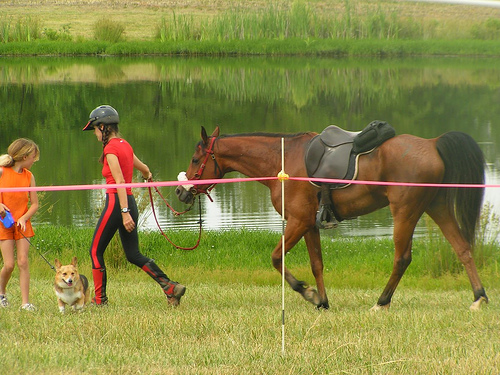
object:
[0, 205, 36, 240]
shorts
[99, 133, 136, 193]
shirt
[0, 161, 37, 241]
outfit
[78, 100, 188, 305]
girl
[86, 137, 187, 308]
outfit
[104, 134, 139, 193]
top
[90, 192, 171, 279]
pants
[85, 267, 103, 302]
stripe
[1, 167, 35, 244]
jumper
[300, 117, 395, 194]
harness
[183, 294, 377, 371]
grass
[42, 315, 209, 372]
grass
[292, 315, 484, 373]
grass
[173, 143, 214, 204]
horse's face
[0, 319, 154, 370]
grass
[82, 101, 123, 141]
woman's head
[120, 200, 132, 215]
woman's wrist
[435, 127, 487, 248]
thick tail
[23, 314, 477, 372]
field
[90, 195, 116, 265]
red stripe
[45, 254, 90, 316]
dog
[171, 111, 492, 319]
horse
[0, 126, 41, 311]
girl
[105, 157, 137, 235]
girl arm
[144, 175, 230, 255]
horse harness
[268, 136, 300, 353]
white stick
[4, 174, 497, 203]
pink rope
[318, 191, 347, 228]
brown stirrup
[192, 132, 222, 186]
rope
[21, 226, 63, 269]
leash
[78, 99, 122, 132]
helmet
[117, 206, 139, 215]
watch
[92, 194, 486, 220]
black pants